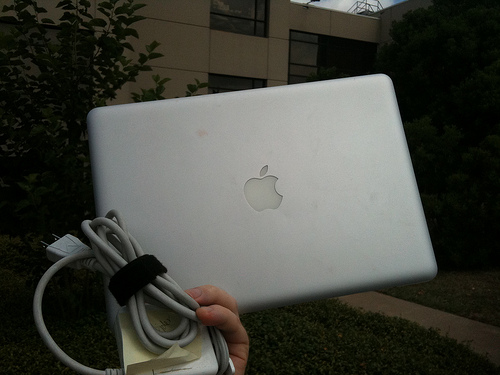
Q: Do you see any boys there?
A: No, there are no boys.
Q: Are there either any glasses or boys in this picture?
A: No, there are no boys or glasses.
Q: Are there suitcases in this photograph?
A: No, there are no suitcases.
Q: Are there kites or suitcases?
A: No, there are no suitcases or kites.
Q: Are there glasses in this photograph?
A: No, there are no glasses.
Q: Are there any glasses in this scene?
A: No, there are no glasses.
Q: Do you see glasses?
A: No, there are no glasses.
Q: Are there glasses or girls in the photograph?
A: No, there are no glasses or girls.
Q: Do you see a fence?
A: No, there are no fences.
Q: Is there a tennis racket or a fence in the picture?
A: No, there are no fences or rackets.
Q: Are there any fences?
A: No, there are no fences.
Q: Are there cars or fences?
A: No, there are no fences or cars.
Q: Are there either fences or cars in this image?
A: No, there are no fences or cars.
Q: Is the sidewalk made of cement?
A: Yes, the sidewalk is made of cement.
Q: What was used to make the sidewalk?
A: The sidewalk is made of cement.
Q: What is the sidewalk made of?
A: The sidewalk is made of concrete.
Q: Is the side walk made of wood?
A: No, the side walk is made of cement.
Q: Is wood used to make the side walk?
A: No, the side walk is made of cement.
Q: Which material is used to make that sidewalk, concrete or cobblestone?
A: The sidewalk is made of concrete.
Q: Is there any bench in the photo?
A: No, there are no benches.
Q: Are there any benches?
A: No, there are no benches.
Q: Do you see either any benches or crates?
A: No, there are no benches or crates.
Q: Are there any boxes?
A: No, there are no boxes.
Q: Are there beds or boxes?
A: No, there are no boxes or beds.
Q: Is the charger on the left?
A: Yes, the charger is on the left of the image.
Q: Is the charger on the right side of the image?
A: No, the charger is on the left of the image.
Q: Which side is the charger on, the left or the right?
A: The charger is on the left of the image.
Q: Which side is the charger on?
A: The charger is on the left of the image.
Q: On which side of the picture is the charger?
A: The charger is on the left of the image.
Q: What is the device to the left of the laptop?
A: The device is a charger.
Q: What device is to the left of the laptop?
A: The device is a charger.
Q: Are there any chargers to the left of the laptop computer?
A: Yes, there is a charger to the left of the laptop computer.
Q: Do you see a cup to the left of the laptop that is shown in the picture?
A: No, there is a charger to the left of the laptop.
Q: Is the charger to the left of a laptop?
A: Yes, the charger is to the left of a laptop.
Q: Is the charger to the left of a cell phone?
A: No, the charger is to the left of a laptop.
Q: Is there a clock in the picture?
A: No, there are no clocks.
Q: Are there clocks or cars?
A: No, there are no clocks or cars.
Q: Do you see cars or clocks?
A: No, there are no clocks or cars.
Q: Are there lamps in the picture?
A: No, there are no lamps.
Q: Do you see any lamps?
A: No, there are no lamps.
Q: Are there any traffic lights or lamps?
A: No, there are no lamps or traffic lights.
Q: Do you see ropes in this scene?
A: No, there are no ropes.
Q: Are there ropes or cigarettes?
A: No, there are no ropes or cigarettes.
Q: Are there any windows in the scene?
A: Yes, there are windows.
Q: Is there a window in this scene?
A: Yes, there are windows.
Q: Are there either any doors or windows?
A: Yes, there are windows.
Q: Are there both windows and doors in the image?
A: No, there are windows but no doors.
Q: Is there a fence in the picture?
A: No, there are no fences.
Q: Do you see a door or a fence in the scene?
A: No, there are no fences or doors.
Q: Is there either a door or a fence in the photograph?
A: No, there are no fences or doors.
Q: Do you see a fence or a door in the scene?
A: No, there are no fences or doors.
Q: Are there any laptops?
A: Yes, there is a laptop.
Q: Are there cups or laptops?
A: Yes, there is a laptop.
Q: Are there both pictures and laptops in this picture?
A: No, there is a laptop but no pictures.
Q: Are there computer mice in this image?
A: No, there are no computer mice.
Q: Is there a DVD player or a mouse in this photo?
A: No, there are no computer mice or DVD players.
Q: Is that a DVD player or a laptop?
A: That is a laptop.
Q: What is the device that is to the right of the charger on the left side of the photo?
A: The device is a laptop.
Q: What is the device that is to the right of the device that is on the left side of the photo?
A: The device is a laptop.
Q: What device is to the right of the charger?
A: The device is a laptop.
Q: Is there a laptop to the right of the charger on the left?
A: Yes, there is a laptop to the right of the charger.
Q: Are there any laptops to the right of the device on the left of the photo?
A: Yes, there is a laptop to the right of the charger.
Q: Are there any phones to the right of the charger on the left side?
A: No, there is a laptop to the right of the charger.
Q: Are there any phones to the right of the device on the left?
A: No, there is a laptop to the right of the charger.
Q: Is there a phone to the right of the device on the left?
A: No, there is a laptop to the right of the charger.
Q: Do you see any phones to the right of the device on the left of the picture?
A: No, there is a laptop to the right of the charger.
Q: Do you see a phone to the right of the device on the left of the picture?
A: No, there is a laptop to the right of the charger.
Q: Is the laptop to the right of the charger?
A: Yes, the laptop is to the right of the charger.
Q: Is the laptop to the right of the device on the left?
A: Yes, the laptop is to the right of the charger.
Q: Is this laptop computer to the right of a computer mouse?
A: No, the laptop computer is to the right of the charger.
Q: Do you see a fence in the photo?
A: No, there are no fences.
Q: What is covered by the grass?
A: The ground is covered by the grass.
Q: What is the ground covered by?
A: The ground is covered by the grass.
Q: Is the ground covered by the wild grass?
A: Yes, the ground is covered by the grass.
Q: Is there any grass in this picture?
A: Yes, there is grass.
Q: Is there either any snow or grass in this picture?
A: Yes, there is grass.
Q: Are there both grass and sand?
A: No, there is grass but no sand.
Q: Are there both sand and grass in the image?
A: No, there is grass but no sand.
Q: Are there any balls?
A: No, there are no balls.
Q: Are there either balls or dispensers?
A: No, there are no balls or dispensers.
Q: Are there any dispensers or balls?
A: No, there are no balls or dispensers.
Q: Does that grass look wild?
A: Yes, the grass is wild.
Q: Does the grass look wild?
A: Yes, the grass is wild.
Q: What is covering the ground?
A: The grass is covering the ground.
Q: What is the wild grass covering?
A: The grass is covering the ground.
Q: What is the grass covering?
A: The grass is covering the ground.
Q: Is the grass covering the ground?
A: Yes, the grass is covering the ground.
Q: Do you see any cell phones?
A: No, there are no cell phones.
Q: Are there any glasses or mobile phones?
A: No, there are no mobile phones or glasses.